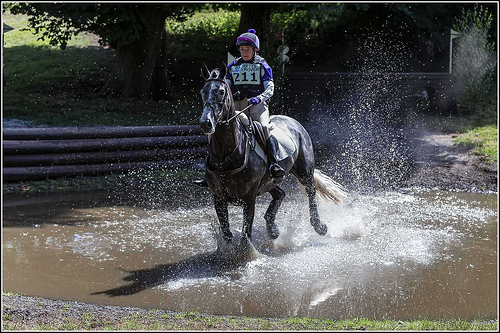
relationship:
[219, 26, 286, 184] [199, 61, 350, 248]
man riding horse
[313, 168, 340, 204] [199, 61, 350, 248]
tail of horse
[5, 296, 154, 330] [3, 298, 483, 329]
stones in grass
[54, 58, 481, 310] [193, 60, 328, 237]
water splashed from horse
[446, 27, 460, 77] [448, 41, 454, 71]
flag on pole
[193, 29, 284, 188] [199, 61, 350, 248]
boy riding horse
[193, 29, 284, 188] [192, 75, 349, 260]
boy riding horse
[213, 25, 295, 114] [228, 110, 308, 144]
boy sitting in saddle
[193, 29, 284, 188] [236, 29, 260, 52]
boy wearing a bonnet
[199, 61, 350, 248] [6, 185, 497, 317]
horse running in water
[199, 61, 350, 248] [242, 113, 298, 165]
horse wearing a saddle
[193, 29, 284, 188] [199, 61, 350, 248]
boy riding a horse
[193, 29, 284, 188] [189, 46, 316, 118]
boy wearing riding outfit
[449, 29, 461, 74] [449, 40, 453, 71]
flag on pole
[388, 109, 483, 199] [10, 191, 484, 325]
path leads to hole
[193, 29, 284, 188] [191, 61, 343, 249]
boy riding horse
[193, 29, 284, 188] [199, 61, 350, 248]
boy on horse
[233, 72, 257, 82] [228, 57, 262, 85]
211 on bib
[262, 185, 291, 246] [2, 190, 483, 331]
leg in water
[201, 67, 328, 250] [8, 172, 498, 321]
horse walking in water